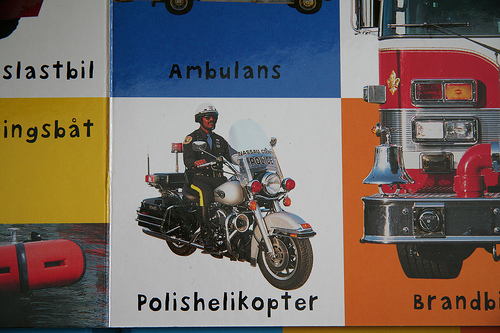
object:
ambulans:
[168, 61, 281, 80]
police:
[183, 103, 240, 259]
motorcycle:
[135, 118, 317, 290]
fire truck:
[348, 0, 500, 279]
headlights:
[412, 115, 478, 144]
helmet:
[195, 103, 220, 123]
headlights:
[262, 173, 282, 196]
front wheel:
[257, 231, 313, 291]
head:
[199, 106, 218, 128]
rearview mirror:
[192, 141, 208, 152]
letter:
[168, 64, 183, 79]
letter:
[186, 65, 202, 79]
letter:
[205, 61, 216, 80]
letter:
[235, 61, 239, 79]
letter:
[243, 65, 254, 79]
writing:
[4, 118, 94, 144]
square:
[0, 97, 109, 224]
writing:
[137, 291, 319, 318]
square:
[107, 98, 344, 330]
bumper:
[358, 196, 499, 246]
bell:
[362, 126, 416, 197]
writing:
[414, 294, 500, 310]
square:
[341, 97, 500, 328]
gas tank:
[214, 181, 244, 207]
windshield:
[228, 117, 273, 170]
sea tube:
[0, 238, 87, 294]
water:
[0, 224, 108, 327]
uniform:
[183, 127, 236, 207]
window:
[378, 0, 499, 36]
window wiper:
[387, 22, 500, 54]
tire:
[395, 243, 463, 279]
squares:
[0, 0, 108, 98]